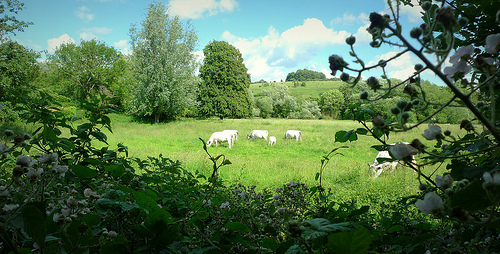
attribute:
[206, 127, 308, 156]
cows — herd, white, grazing, together, hungry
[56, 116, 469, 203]
pasture — lush, green, grassy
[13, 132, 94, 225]
flowers — white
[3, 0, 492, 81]
sky — blue, cloudy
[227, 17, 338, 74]
clouds — puffy, white, fluffy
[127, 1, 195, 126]
tree — taller, green, large, full, tall, wide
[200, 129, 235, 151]
cow — white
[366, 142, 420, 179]
cow — alone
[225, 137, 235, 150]
legs — hind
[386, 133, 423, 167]
flower — white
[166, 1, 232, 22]
cloud — white, bright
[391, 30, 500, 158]
flowers — white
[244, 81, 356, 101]
hills — rolling